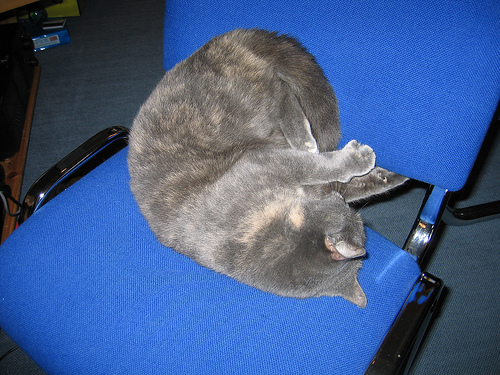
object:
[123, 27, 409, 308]
cat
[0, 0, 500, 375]
chair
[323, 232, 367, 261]
ear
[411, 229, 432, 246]
reflection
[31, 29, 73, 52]
trash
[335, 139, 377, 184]
paw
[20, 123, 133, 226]
armrest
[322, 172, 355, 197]
whiskers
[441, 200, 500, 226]
lever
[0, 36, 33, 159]
electronics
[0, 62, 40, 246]
shelf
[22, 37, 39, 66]
dials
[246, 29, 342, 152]
tail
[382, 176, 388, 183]
claws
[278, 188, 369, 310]
head